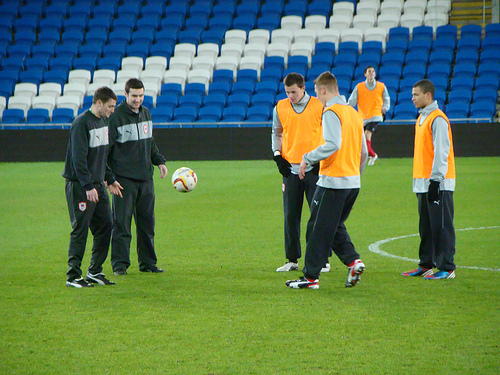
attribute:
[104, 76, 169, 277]
man — playing, standing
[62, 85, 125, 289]
man — playing, standing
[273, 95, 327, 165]
vest — yellow, orange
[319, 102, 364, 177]
vest — yellow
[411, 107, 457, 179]
vest — yellow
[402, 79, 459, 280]
man — watching, standing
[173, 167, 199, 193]
ball — red, white, airborne, round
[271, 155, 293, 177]
glove — black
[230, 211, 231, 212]
grass — green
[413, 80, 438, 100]
hair — short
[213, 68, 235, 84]
seat — blue, empty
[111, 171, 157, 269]
pants — black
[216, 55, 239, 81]
seat — white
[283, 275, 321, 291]
shoe — white, black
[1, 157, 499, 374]
field — green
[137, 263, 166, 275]
shoe — black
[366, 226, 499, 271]
line — white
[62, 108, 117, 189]
shirt — black